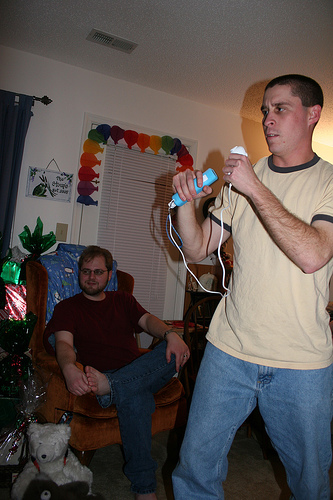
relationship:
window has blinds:
[72, 85, 205, 243] [70, 112, 201, 254]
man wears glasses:
[55, 244, 191, 500] [80, 266, 117, 277]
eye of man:
[252, 104, 301, 116] [170, 74, 333, 500]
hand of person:
[170, 164, 231, 258] [164, 54, 330, 323]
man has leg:
[170, 74, 333, 500] [173, 340, 254, 498]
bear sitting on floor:
[2, 412, 86, 474] [95, 458, 120, 487]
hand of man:
[224, 157, 258, 190] [170, 74, 333, 500]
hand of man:
[219, 150, 265, 194] [170, 74, 333, 500]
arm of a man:
[175, 198, 231, 261] [170, 74, 333, 500]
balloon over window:
[81, 181, 93, 201] [108, 144, 163, 319]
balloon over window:
[74, 165, 103, 181] [79, 122, 184, 319]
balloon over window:
[110, 125, 125, 144] [96, 143, 176, 319]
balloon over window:
[79, 154, 101, 168] [105, 158, 163, 246]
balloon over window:
[134, 128, 148, 152] [76, 118, 176, 317]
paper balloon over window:
[76, 150, 105, 168] [74, 114, 186, 325]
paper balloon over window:
[123, 128, 137, 148] [95, 142, 175, 347]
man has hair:
[178, 64, 327, 496] [258, 66, 326, 110]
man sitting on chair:
[55, 244, 191, 500] [24, 239, 189, 490]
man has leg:
[32, 205, 162, 454] [83, 340, 176, 400]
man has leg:
[32, 205, 162, 454] [113, 381, 153, 496]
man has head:
[170, 74, 333, 500] [254, 73, 324, 168]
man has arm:
[170, 74, 333, 500] [218, 171, 326, 273]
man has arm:
[170, 74, 333, 500] [222, 152, 332, 273]